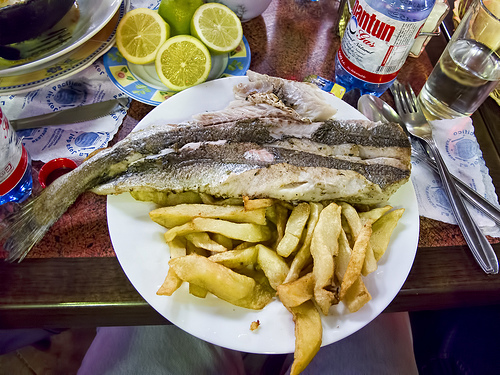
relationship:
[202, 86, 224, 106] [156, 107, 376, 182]
plate has fish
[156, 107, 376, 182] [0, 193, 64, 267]
fish has tail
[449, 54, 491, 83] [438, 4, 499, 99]
liquid in glass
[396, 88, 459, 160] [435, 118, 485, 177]
fork on napkin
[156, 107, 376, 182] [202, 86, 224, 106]
fish on plate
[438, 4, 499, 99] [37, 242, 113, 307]
glass on table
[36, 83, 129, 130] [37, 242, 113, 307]
knife on table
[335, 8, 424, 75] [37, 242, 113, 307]
bottle on table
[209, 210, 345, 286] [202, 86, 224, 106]
french fries on plate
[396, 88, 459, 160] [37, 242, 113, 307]
fork on table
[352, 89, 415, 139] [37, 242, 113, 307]
spoon on table